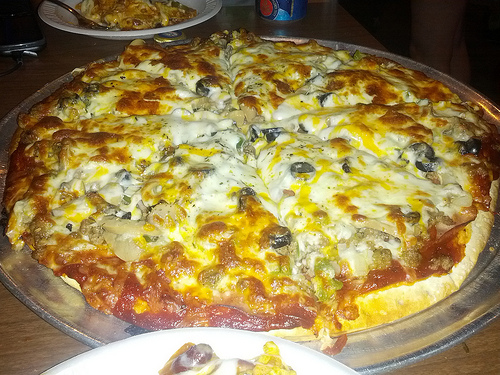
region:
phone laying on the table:
[0, 14, 52, 56]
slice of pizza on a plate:
[173, 343, 256, 371]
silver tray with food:
[7, 56, 491, 337]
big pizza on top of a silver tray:
[1, 36, 496, 333]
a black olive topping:
[264, 225, 297, 253]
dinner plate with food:
[37, 1, 204, 48]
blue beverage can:
[250, 0, 310, 26]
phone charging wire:
[3, 51, 35, 80]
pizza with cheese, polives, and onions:
[12, 46, 477, 308]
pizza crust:
[324, 209, 494, 334]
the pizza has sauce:
[103, 297, 297, 330]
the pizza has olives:
[270, 225, 297, 254]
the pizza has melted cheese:
[279, 157, 409, 229]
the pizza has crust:
[327, 265, 462, 333]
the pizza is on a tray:
[350, 270, 491, 370]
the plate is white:
[48, 326, 389, 373]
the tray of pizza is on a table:
[2, 282, 92, 370]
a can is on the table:
[249, 0, 324, 30]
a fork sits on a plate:
[32, 0, 131, 42]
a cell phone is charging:
[4, 0, 56, 78]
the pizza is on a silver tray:
[0, 25, 498, 366]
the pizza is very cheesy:
[6, 33, 498, 335]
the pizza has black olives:
[89, 65, 489, 271]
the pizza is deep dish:
[0, 33, 495, 366]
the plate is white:
[36, 0, 231, 45]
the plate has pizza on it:
[28, 320, 367, 373]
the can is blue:
[251, 1, 308, 25]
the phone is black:
[1, 0, 50, 72]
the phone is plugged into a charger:
[0, 2, 47, 84]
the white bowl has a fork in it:
[38, 0, 108, 34]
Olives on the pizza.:
[276, 161, 330, 181]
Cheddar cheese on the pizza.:
[351, 125, 388, 161]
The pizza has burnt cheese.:
[360, 73, 397, 107]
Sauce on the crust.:
[229, 315, 281, 337]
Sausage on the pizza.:
[360, 246, 401, 271]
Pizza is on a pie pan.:
[383, 320, 444, 353]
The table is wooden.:
[440, 340, 486, 369]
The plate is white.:
[78, 343, 142, 374]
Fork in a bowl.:
[49, 3, 113, 40]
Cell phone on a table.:
[0, 11, 58, 64]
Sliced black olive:
[284, 155, 320, 180]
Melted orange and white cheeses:
[313, 177, 392, 206]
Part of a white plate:
[99, 325, 261, 342]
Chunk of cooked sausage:
[368, 246, 395, 271]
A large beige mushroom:
[103, 215, 166, 262]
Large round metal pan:
[1, 33, 499, 373]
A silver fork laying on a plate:
[32, 5, 112, 35]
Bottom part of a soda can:
[256, 0, 307, 27]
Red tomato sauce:
[206, 301, 313, 328]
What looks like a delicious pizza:
[3, 30, 498, 328]